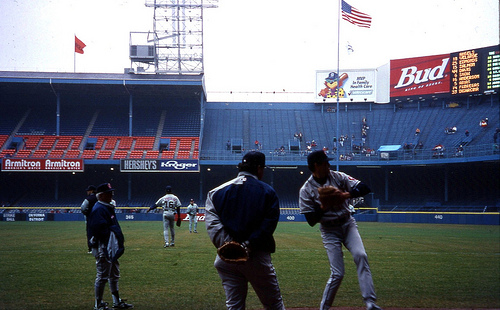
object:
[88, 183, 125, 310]
man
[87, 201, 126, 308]
uniform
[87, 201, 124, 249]
jacket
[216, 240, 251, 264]
glove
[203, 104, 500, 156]
seats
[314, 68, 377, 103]
advertisement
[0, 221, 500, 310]
grass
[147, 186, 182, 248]
player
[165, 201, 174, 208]
number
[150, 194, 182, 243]
uniform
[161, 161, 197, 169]
logo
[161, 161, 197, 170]
kroger sign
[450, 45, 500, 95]
scoreboard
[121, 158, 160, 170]
banner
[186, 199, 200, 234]
team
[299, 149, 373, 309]
baseball player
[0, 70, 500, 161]
upper deck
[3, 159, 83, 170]
logo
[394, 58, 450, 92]
logo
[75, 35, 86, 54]
red flag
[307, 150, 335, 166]
hat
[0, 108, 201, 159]
seats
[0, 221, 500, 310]
field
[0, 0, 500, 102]
cloudy sky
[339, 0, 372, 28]
american flag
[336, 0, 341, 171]
pole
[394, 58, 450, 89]
bud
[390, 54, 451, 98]
billboard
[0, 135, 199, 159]
deck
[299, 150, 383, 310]
man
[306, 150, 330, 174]
head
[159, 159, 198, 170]
hersheys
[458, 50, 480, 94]
names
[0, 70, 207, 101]
awning